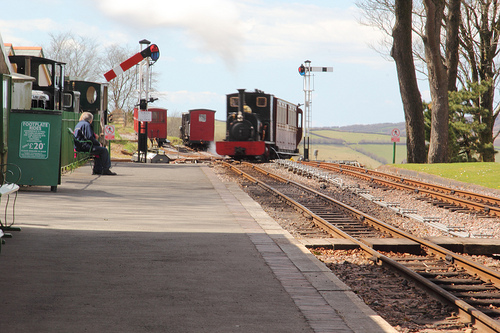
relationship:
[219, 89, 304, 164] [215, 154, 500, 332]
train on tracks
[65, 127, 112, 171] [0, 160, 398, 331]
bench on platform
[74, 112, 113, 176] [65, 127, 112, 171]
man sitting on bench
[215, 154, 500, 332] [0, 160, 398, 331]
tracks by platform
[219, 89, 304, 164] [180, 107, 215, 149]
train by train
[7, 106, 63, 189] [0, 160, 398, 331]
trash can on platform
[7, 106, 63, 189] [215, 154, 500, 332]
trash can near tracks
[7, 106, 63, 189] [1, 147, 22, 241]
trash can near a bench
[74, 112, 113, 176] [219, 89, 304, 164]
man waiting for train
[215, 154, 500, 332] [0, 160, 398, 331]
tracks are near platform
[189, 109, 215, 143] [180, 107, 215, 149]
rear of train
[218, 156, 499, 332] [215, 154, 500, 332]
gravel between tracks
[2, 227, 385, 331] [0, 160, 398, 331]
shadow on platform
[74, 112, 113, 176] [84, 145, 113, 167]
man wearing pants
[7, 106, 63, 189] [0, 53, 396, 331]
trash can at train station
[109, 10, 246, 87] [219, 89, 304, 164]
smoke from train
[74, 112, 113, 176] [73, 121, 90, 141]
man wearing a shirt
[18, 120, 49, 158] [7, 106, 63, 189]
ticket sign on trash can